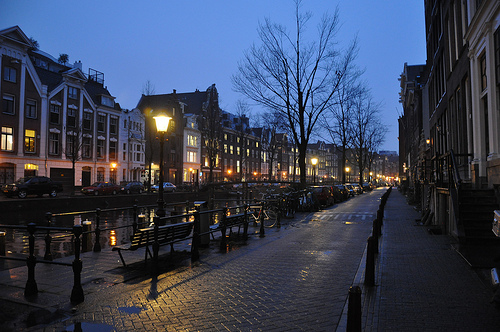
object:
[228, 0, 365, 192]
tree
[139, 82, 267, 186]
buildings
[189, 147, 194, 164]
windows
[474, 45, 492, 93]
window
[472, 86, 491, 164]
frame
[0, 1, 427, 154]
sky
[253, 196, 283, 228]
cycle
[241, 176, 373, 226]
parking area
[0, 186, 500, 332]
road